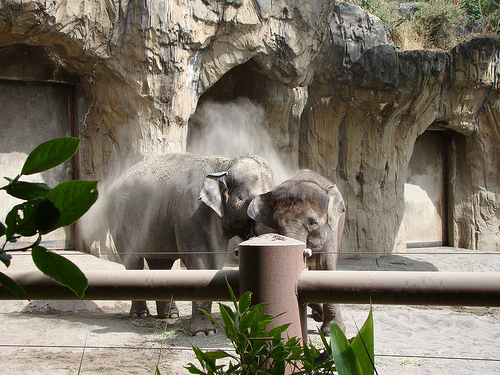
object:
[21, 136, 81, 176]
leaf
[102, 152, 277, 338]
elephant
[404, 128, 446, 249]
door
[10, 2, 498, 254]
wall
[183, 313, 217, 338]
foot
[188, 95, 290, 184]
water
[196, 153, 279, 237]
head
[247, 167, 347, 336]
elephant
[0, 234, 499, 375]
fence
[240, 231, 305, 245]
dirt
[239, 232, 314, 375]
post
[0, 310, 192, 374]
floor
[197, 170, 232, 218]
ear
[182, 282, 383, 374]
tree